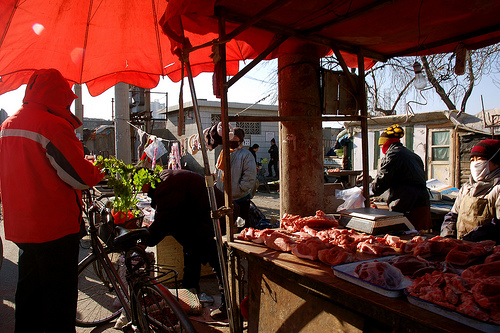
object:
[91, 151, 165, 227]
plants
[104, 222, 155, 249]
seat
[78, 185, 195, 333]
bicycle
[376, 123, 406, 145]
hat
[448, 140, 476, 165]
ground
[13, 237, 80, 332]
black pants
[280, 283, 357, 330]
shade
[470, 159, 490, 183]
face mask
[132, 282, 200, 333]
wheel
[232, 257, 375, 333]
board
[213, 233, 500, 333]
board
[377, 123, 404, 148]
marvin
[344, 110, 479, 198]
trailer home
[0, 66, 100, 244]
jacket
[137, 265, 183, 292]
basket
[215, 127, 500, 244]
people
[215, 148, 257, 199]
jacket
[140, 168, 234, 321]
man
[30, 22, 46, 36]
bulb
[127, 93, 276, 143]
line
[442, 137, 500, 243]
female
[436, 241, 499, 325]
meat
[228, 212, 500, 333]
display counter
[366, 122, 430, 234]
man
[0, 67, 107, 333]
man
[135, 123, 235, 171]
clothes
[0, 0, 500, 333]
food market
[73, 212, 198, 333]
plats